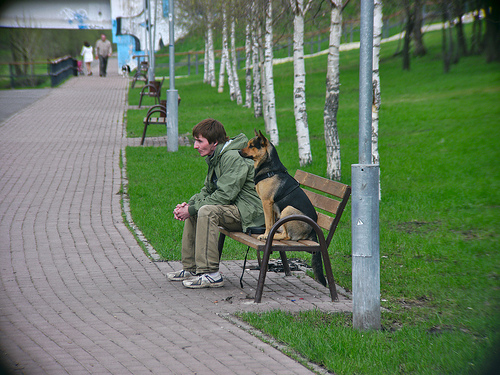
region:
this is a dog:
[232, 132, 326, 246]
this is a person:
[164, 105, 261, 306]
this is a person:
[94, 28, 121, 80]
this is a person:
[65, 34, 100, 80]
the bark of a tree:
[356, 0, 402, 213]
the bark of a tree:
[324, 0, 352, 194]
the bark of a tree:
[287, 8, 325, 170]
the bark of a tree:
[261, 18, 288, 148]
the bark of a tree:
[247, 10, 264, 124]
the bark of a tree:
[211, 5, 241, 113]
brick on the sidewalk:
[102, 276, 114, 295]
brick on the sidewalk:
[255, 355, 275, 370]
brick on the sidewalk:
[172, 355, 192, 373]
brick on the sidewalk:
[105, 351, 120, 367]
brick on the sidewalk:
[166, 313, 184, 334]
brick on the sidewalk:
[68, 293, 89, 313]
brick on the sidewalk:
[34, 250, 56, 274]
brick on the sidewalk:
[111, 266, 131, 285]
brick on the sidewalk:
[78, 200, 90, 222]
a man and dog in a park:
[24, 20, 460, 297]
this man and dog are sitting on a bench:
[118, 120, 355, 289]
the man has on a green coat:
[137, 89, 255, 322]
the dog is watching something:
[218, 117, 328, 267]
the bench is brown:
[109, 58, 229, 163]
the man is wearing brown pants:
[165, 202, 258, 276]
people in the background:
[61, 9, 128, 72]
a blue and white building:
[102, 8, 169, 76]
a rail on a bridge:
[22, 37, 70, 96]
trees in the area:
[174, 15, 409, 122]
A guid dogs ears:
[250, 125, 272, 146]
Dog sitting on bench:
[239, 124, 326, 249]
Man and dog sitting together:
[179, 120, 359, 306]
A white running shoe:
[180, 270, 225, 291]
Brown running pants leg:
[193, 205, 225, 281]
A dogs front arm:
[256, 177, 282, 239]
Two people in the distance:
[75, 32, 115, 76]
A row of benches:
[120, 52, 182, 150]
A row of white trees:
[180, 11, 407, 154]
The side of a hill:
[382, 73, 482, 180]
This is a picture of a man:
[85, 91, 345, 263]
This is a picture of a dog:
[235, 124, 398, 329]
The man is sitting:
[158, 149, 258, 228]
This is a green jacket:
[176, 129, 293, 243]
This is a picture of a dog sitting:
[208, 87, 338, 280]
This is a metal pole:
[354, 164, 492, 309]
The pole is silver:
[345, 113, 443, 197]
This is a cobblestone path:
[30, 212, 137, 313]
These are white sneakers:
[167, 259, 249, 300]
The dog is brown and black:
[246, 160, 343, 230]